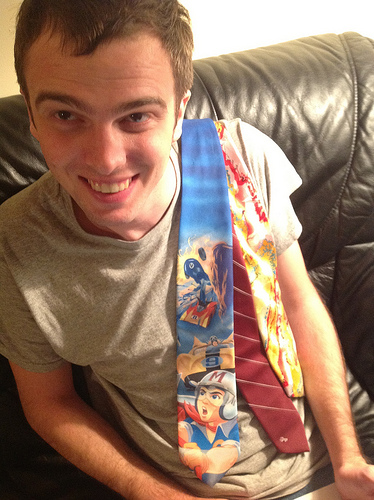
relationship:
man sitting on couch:
[1, 0, 373, 497] [208, 38, 372, 369]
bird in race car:
[183, 255, 216, 301] [179, 297, 218, 328]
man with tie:
[1, 0, 373, 497] [176, 118, 240, 486]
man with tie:
[1, 0, 373, 497] [231, 207, 308, 453]